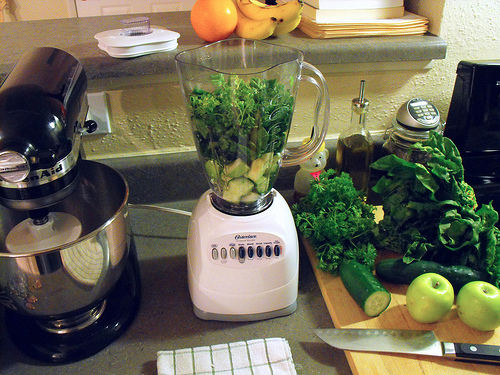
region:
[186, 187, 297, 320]
A grinder mixer on counter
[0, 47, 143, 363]
A food processer on kitchen counter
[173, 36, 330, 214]
A juicer jar with veggies inside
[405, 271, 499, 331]
Green apples on a wooden board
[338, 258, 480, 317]
A cucumber and a half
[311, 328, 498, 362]
Knife on the wooden board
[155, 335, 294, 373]
Kitchen napkin of cloth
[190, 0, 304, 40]
An orange and a few bananas on a shelf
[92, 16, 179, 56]
Lid of the juice jar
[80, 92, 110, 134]
Electrical connection point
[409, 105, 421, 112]
small white colored button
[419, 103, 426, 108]
small white colored button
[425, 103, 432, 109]
small white colored button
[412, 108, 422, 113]
small white colored button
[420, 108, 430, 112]
small white colored button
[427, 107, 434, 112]
small white colored button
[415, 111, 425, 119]
small white colored button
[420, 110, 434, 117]
small white colored button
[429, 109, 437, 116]
small white colored button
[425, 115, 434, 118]
small white colored button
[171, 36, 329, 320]
a blender on a kitchen counter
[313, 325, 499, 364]
a knife on a wooden cutting board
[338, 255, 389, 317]
a half cucumber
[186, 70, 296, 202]
green veggies inside a blender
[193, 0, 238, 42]
an orange on a shelf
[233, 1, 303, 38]
a bunch of yellow bananas on a shelf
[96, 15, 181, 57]
white lid of a blender on a shelf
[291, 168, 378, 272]
a bunch of parsley leaves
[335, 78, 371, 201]
a bottle of olive oil on a counter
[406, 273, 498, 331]
two green apples on a cutting board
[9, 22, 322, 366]
Two kitchen appliances on the counter.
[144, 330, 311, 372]
A dish towel on the counter.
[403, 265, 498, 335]
Two green apples.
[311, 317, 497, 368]
A large cutting knife.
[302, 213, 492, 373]
A wooden cutting board.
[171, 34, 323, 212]
Assorted vegetables in a blender.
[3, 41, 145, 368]
A stainless steel mixer.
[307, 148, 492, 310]
Green vegetables laying on a cutting board.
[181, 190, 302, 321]
The white base of a blender.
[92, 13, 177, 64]
The white lid to the blender.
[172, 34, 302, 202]
several vegetables in a blender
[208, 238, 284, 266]
the buttons on a blender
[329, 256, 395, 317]
a cucumber sliced in half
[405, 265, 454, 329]
a green apple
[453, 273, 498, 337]
a green apple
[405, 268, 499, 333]
two green apples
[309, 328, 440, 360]
the blade of a knife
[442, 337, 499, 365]
the handle of a knife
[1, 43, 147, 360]
a KitchenAid mixer and bowl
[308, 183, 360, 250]
a bunch of parsley